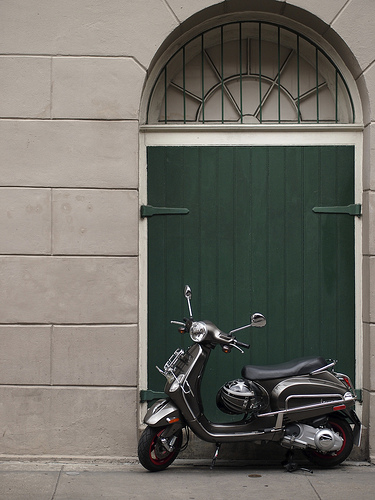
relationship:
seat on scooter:
[244, 354, 330, 380] [135, 283, 361, 468]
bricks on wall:
[4, 189, 132, 322] [1, 4, 137, 455]